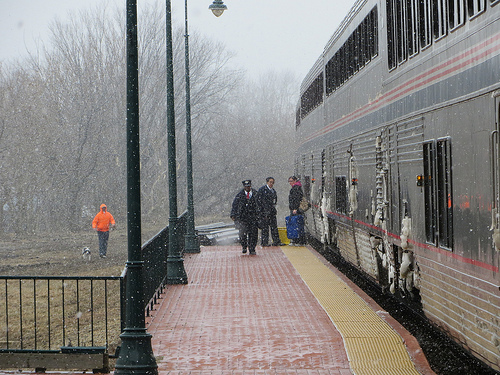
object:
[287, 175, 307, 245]
woman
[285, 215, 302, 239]
suitcase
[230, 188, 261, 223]
uniform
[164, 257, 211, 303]
ground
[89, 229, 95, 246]
leash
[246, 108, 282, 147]
snow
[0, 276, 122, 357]
fence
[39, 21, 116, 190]
bare trees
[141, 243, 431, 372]
platform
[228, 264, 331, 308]
ground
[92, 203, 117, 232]
coat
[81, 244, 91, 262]
dog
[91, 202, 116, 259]
man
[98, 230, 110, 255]
pants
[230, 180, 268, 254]
conductor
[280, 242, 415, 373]
stripe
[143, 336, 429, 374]
ground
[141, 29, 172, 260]
tree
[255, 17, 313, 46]
grey sky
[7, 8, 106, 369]
snow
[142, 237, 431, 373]
pavement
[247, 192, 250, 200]
tie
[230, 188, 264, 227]
coat